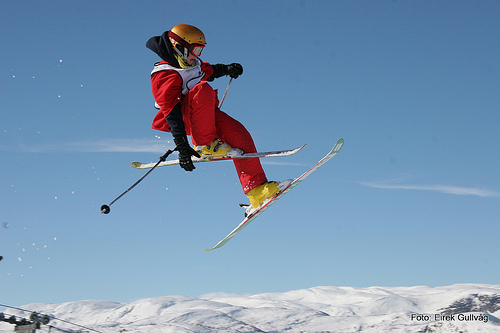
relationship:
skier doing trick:
[137, 17, 303, 215] [80, 15, 360, 257]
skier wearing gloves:
[137, 17, 303, 215] [171, 63, 246, 172]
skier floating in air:
[137, 17, 303, 215] [7, 3, 500, 323]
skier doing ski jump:
[137, 17, 303, 215] [80, 15, 360, 257]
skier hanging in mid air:
[137, 17, 303, 215] [80, 15, 360, 257]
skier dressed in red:
[137, 17, 303, 215] [144, 56, 273, 196]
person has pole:
[137, 17, 303, 215] [97, 145, 180, 214]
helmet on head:
[167, 22, 213, 60] [148, 21, 210, 70]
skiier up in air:
[137, 17, 303, 215] [7, 3, 500, 323]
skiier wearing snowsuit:
[137, 17, 303, 215] [144, 56, 273, 196]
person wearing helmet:
[137, 17, 303, 215] [167, 22, 213, 60]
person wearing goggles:
[137, 17, 303, 215] [183, 40, 205, 62]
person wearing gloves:
[137, 17, 303, 215] [171, 63, 246, 172]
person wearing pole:
[137, 17, 303, 215] [97, 145, 180, 214]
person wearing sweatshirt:
[137, 17, 303, 215] [148, 56, 224, 118]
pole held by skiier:
[89, 145, 180, 217] [137, 17, 303, 215]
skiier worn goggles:
[137, 17, 303, 215] [183, 40, 205, 62]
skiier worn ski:
[137, 17, 303, 215] [125, 130, 353, 255]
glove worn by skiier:
[171, 63, 246, 172] [137, 17, 303, 215]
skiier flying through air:
[137, 17, 303, 215] [7, 3, 500, 323]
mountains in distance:
[1, 281, 499, 332] [0, 67, 483, 227]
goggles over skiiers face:
[183, 40, 205, 62] [194, 50, 199, 105]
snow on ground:
[1, 281, 499, 332] [2, 200, 494, 321]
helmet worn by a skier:
[167, 22, 213, 60] [149, 23, 295, 215]